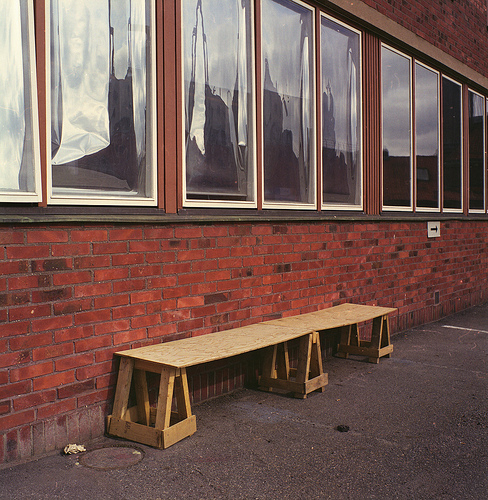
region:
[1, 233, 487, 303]
A brick wall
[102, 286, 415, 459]
A wooden bench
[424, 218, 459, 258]
A forward sign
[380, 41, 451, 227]
A glass window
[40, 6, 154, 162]
Curtains in a window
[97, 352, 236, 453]
A board holder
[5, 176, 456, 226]
A window shield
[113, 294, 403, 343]
A thin brown board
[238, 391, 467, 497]
A hard rock pavement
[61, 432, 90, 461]
A piece of trash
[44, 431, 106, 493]
crumbled piece of trash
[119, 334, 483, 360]
a wood make shift bench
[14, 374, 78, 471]
wall made of brick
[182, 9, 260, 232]
reflection on window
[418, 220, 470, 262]
arrow pointing to the right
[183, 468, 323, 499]
pavement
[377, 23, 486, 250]
four windows on the building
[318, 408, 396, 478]
something black on the ground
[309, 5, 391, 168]
window frame is brown and white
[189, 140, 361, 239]
three windows on building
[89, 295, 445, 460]
A wooden make shift bench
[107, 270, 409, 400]
A sheet of wood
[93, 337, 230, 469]
A wooden leg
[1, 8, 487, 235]
Windows in front of the building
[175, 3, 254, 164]
Curtains inside the window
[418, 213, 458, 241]
A sign with an arrow pointing right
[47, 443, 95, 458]
Crumbled up paper on the floor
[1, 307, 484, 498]
Paved sidewalk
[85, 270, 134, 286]
Bricks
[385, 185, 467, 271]
A sign on the building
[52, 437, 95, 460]
A white piece of trash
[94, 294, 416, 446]
A wooden bench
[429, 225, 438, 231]
A black arrow on a sign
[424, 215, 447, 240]
A white rectangle sign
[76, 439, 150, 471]
A circle shape on a sidewalk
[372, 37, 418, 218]
A window on a building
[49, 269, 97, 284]
A red brick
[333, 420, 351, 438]
A black rock on the ground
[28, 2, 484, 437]
A building made of bricks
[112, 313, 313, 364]
A piece of plywood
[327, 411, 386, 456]
something black on the ground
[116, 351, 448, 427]
a make shift bench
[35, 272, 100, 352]
the wall is brick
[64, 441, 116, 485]
crumpled trash on ground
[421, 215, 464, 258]
the arrow points to the right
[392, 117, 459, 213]
reflections shown on windows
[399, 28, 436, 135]
the window frame is brown and white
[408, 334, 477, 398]
things drawn in chalk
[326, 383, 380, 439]
cigarette butt on ground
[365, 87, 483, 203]
sky looks cloudy in reflection